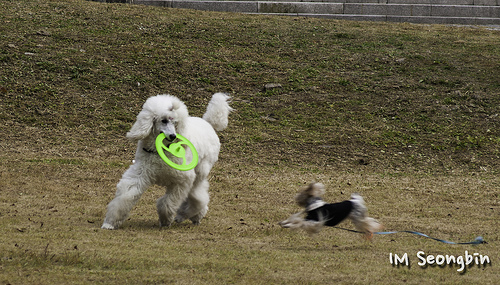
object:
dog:
[100, 92, 235, 230]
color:
[192, 126, 207, 144]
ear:
[125, 108, 156, 140]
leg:
[101, 164, 156, 230]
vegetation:
[297, 106, 496, 157]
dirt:
[0, 231, 233, 283]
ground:
[0, 0, 497, 282]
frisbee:
[155, 133, 199, 172]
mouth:
[160, 124, 177, 142]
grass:
[297, 237, 379, 282]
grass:
[3, 233, 132, 283]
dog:
[278, 182, 386, 240]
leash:
[373, 230, 489, 244]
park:
[0, 0, 500, 285]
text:
[388, 250, 491, 272]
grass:
[21, 33, 444, 84]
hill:
[0, 0, 500, 83]